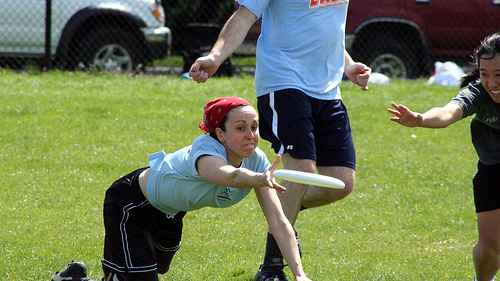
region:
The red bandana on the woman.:
[189, 83, 244, 120]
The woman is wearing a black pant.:
[84, 156, 192, 267]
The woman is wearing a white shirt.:
[144, 135, 255, 215]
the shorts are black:
[252, 77, 363, 179]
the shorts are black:
[251, 65, 362, 187]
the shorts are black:
[255, 71, 363, 188]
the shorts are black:
[241, 69, 372, 187]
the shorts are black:
[244, 69, 376, 187]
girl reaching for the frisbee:
[171, 93, 360, 202]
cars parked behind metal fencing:
[4, 0, 494, 80]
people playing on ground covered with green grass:
[7, 3, 494, 274]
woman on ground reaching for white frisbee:
[79, 94, 346, 273]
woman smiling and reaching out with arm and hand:
[385, 30, 492, 274]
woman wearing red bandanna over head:
[195, 92, 262, 157]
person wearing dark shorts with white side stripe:
[252, 80, 359, 170]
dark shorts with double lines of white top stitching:
[80, 166, 185, 277]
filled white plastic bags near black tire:
[350, 13, 465, 87]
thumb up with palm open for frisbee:
[263, 146, 345, 193]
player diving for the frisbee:
[51, 97, 312, 278]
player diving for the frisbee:
[385, 28, 497, 278]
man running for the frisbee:
[190, 0, 370, 280]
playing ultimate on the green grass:
[7, 71, 497, 276]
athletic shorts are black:
[98, 171, 183, 277]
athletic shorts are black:
[250, 80, 360, 166]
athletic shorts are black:
[472, 159, 499, 215]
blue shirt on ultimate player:
[235, 1, 350, 97]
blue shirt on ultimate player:
[139, 137, 263, 209]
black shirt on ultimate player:
[457, 83, 498, 173]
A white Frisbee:
[275, 160, 351, 195]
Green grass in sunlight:
[68, 95, 143, 149]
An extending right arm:
[375, 78, 462, 147]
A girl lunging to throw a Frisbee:
[90, 94, 353, 251]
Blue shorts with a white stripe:
[251, 94, 371, 164]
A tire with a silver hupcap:
[78, 28, 145, 78]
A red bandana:
[194, 90, 244, 137]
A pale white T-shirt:
[258, 10, 348, 98]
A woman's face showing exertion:
[231, 112, 261, 154]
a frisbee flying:
[265, 155, 357, 190]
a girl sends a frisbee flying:
[56, 95, 351, 277]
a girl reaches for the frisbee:
[391, 26, 492, 271]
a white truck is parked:
[11, 10, 184, 68]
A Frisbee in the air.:
[269, 166, 351, 189]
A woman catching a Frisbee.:
[91, 96, 357, 278]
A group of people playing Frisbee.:
[73, 5, 495, 279]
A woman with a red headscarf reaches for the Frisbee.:
[94, 97, 343, 279]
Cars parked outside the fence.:
[8, 2, 498, 87]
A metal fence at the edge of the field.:
[6, 3, 494, 90]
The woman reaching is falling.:
[54, 95, 350, 278]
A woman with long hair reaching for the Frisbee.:
[388, 20, 497, 279]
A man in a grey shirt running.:
[191, 3, 361, 278]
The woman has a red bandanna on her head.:
[193, 88, 266, 174]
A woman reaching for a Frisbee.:
[43, 92, 358, 278]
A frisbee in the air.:
[269, 165, 351, 192]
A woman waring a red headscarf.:
[93, 96, 306, 275]